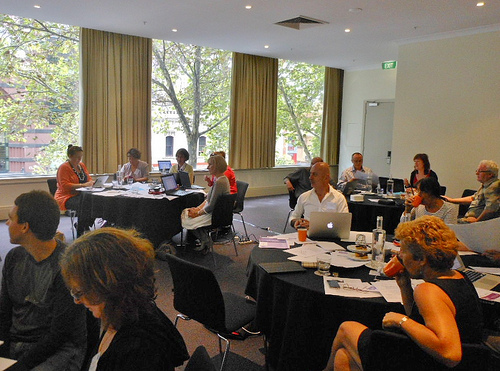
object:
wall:
[396, 52, 487, 149]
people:
[54, 144, 96, 235]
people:
[119, 148, 150, 185]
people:
[168, 148, 193, 185]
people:
[181, 155, 231, 254]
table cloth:
[75, 188, 206, 251]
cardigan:
[54, 160, 93, 210]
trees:
[0, 14, 324, 175]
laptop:
[306, 211, 352, 240]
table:
[76, 181, 206, 247]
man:
[288, 162, 350, 231]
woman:
[203, 150, 238, 193]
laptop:
[159, 173, 194, 198]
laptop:
[177, 170, 206, 190]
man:
[0, 189, 87, 369]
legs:
[326, 320, 374, 370]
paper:
[257, 230, 424, 305]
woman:
[56, 226, 187, 371]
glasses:
[67, 285, 93, 299]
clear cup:
[316, 253, 332, 273]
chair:
[163, 253, 267, 371]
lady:
[324, 214, 485, 371]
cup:
[382, 254, 405, 277]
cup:
[297, 228, 307, 241]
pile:
[282, 241, 373, 269]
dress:
[354, 269, 489, 371]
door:
[360, 100, 396, 179]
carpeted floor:
[238, 188, 295, 243]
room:
[0, 0, 500, 371]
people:
[336, 152, 379, 192]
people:
[400, 176, 454, 224]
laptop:
[83, 176, 110, 190]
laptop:
[157, 160, 173, 175]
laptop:
[450, 253, 500, 299]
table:
[342, 189, 405, 230]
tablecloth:
[243, 242, 403, 343]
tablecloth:
[344, 194, 405, 233]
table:
[243, 230, 500, 371]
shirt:
[288, 183, 349, 226]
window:
[273, 57, 324, 167]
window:
[150, 38, 231, 171]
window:
[0, 12, 83, 179]